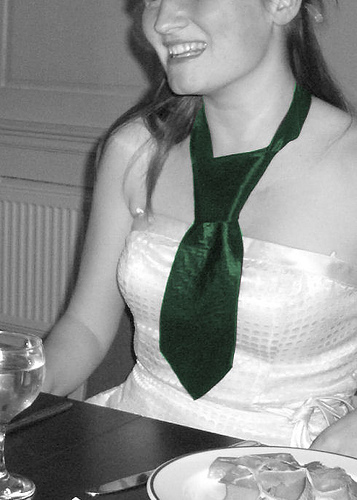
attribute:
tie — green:
[158, 78, 312, 402]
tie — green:
[163, 162, 308, 412]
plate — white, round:
[146, 444, 356, 499]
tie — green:
[152, 97, 302, 401]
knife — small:
[95, 439, 263, 495]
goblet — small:
[0, 325, 46, 498]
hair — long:
[64, 18, 326, 235]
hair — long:
[111, 0, 351, 223]